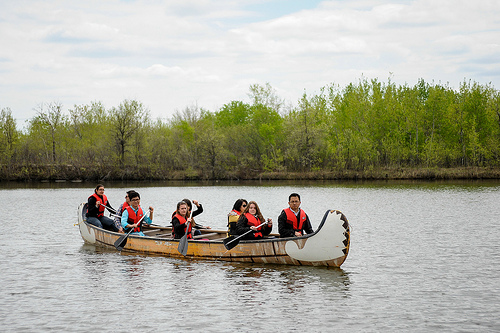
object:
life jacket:
[283, 207, 307, 233]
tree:
[242, 81, 288, 173]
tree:
[325, 81, 385, 172]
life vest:
[86, 193, 107, 217]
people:
[171, 200, 204, 239]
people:
[236, 201, 273, 240]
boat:
[78, 201, 351, 267]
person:
[227, 199, 248, 233]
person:
[171, 199, 204, 240]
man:
[85, 184, 117, 231]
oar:
[101, 204, 118, 213]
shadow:
[79, 244, 354, 307]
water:
[0, 180, 500, 333]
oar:
[222, 221, 269, 251]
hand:
[250, 225, 258, 231]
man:
[121, 193, 154, 236]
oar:
[177, 202, 194, 256]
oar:
[114, 209, 151, 251]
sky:
[0, 0, 500, 132]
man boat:
[113, 190, 136, 231]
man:
[278, 193, 315, 239]